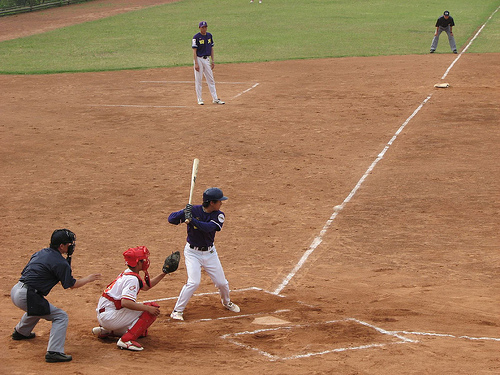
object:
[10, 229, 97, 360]
catcher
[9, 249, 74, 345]
uniform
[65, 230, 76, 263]
mask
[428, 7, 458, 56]
umpire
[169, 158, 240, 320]
batter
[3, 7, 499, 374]
field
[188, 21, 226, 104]
man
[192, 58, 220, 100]
pants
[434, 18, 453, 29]
shirt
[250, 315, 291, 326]
plate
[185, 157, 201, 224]
bat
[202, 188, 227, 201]
helmet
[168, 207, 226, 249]
blue uniform